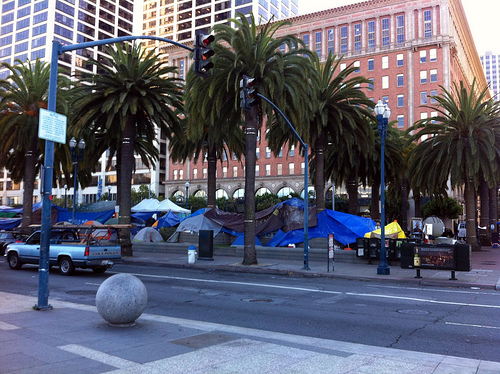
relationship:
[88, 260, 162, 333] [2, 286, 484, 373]
ball on sidewalk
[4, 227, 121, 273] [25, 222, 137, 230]
truck with ladder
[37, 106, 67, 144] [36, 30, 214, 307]
sign on traffic pole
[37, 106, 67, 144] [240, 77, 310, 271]
sign on traffic pole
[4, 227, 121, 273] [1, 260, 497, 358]
truck in street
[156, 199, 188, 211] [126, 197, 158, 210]
white tents surrounded by white tents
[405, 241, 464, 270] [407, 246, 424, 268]
ad with bottle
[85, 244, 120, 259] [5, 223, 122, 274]
back of truck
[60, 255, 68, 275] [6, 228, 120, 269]
tire on truck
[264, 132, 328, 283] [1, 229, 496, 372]
pole on ground